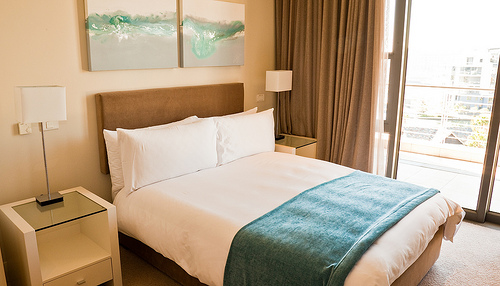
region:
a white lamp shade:
[12, 83, 70, 125]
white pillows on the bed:
[101, 105, 276, 201]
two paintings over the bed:
[80, 0, 247, 72]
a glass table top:
[9, 188, 108, 233]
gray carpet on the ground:
[117, 215, 499, 283]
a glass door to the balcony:
[371, 0, 498, 213]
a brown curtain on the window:
[271, 0, 388, 173]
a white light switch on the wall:
[251, 91, 267, 103]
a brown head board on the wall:
[91, 80, 246, 176]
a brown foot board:
[386, 221, 446, 284]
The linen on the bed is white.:
[123, 150, 330, 240]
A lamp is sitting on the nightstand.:
[23, 83, 113, 238]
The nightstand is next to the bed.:
[16, 176, 176, 281]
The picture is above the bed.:
[58, 3, 260, 75]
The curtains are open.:
[286, 0, 411, 172]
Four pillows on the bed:
[113, 103, 285, 185]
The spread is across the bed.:
[226, 175, 471, 262]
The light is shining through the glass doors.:
[388, 9, 498, 211]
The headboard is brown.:
[96, 91, 280, 151]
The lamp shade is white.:
[12, 81, 76, 131]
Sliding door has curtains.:
[280, 0, 498, 238]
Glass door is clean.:
[378, 0, 499, 220]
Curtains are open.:
[266, 2, 384, 184]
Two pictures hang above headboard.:
[63, 0, 268, 97]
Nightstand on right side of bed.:
[251, 130, 319, 187]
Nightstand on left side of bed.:
[0, 175, 132, 284]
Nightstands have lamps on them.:
[0, 77, 328, 284]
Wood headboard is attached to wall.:
[65, 78, 290, 213]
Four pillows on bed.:
[96, 100, 298, 195]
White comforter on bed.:
[95, 137, 476, 284]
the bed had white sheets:
[106, 106, 463, 282]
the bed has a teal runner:
[221, 167, 445, 282]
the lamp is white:
[18, 85, 65, 200]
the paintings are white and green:
[82, 0, 246, 68]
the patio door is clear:
[399, 0, 494, 220]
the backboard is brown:
[96, 79, 245, 173]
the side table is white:
[8, 185, 124, 284]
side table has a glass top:
[8, 187, 105, 229]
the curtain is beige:
[277, 0, 378, 180]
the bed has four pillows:
[103, 105, 280, 197]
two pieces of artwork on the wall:
[74, 1, 256, 77]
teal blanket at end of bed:
[222, 167, 432, 284]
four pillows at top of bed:
[106, 102, 263, 190]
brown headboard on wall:
[81, 82, 256, 189]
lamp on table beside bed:
[12, 74, 79, 214]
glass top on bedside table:
[5, 189, 119, 259]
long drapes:
[273, 0, 404, 175]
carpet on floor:
[442, 220, 498, 284]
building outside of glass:
[401, 52, 496, 158]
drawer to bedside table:
[45, 262, 111, 284]